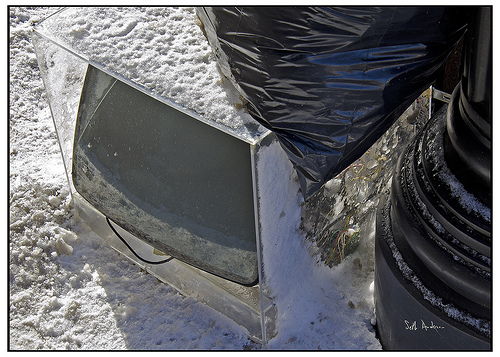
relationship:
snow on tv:
[6, 7, 492, 351] [24, 14, 367, 339]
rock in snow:
[54, 190, 62, 197] [6, 164, 62, 295]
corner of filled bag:
[229, 185, 447, 357] [193, 5, 480, 203]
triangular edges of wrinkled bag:
[182, 98, 443, 357] [193, 5, 480, 203]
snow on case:
[6, 7, 492, 351] [22, 0, 387, 320]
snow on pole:
[6, 7, 492, 351] [366, 9, 498, 356]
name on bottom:
[400, 311, 452, 338] [350, 289, 499, 352]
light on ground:
[48, 267, 109, 332] [27, 238, 123, 304]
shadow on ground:
[101, 270, 367, 352] [11, 6, 381, 348]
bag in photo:
[193, 5, 480, 203] [19, 11, 493, 352]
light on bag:
[246, 40, 309, 107] [276, 28, 353, 75]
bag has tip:
[187, 7, 437, 207] [279, 154, 359, 274]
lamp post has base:
[461, 6, 492, 137] [373, 91, 495, 354]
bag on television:
[193, 5, 480, 203] [28, 6, 437, 346]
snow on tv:
[121, 15, 192, 61] [24, 14, 367, 339]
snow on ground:
[6, 7, 492, 351] [19, 225, 177, 352]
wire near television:
[105, 216, 175, 266] [28, 6, 437, 346]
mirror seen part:
[76, 79, 255, 253] [177, 153, 200, 178]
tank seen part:
[372, 87, 498, 354] [406, 264, 438, 302]